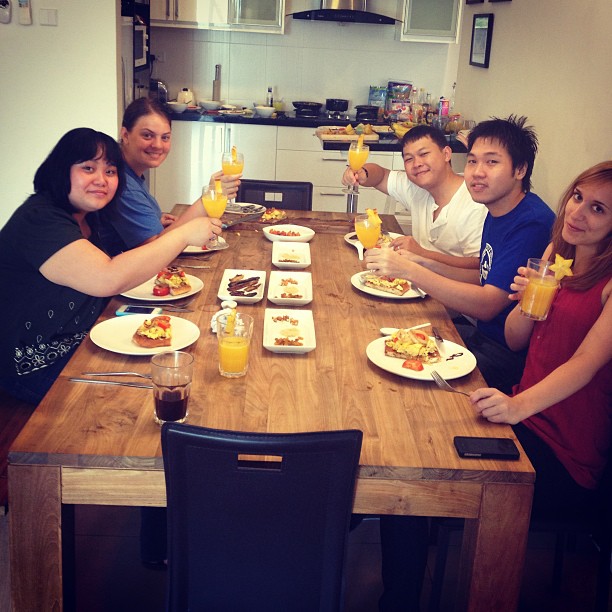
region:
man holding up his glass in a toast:
[340, 119, 491, 270]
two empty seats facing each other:
[155, 171, 366, 609]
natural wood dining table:
[2, 199, 542, 610]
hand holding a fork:
[428, 367, 523, 428]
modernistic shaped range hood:
[283, 0, 408, 29]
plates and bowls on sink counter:
[163, 96, 278, 118]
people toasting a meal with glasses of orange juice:
[0, 94, 611, 510]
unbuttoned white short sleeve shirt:
[385, 167, 489, 257]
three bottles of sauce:
[406, 84, 435, 125]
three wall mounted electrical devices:
[0, 0, 61, 28]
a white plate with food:
[88, 314, 200, 355]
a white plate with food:
[117, 271, 201, 301]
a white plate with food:
[185, 233, 222, 253]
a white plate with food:
[340, 231, 407, 249]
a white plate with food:
[348, 270, 422, 299]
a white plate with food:
[366, 335, 476, 383]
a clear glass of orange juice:
[212, 312, 253, 378]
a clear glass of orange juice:
[199, 182, 226, 250]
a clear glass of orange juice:
[516, 254, 564, 321]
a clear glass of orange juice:
[347, 210, 381, 278]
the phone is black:
[452, 432, 519, 461]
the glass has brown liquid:
[149, 349, 190, 424]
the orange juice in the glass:
[215, 311, 252, 378]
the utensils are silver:
[67, 365, 158, 390]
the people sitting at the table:
[1, 95, 608, 469]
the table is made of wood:
[9, 201, 536, 608]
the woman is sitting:
[431, 159, 609, 611]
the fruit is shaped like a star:
[547, 253, 575, 280]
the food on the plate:
[365, 330, 476, 381]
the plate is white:
[366, 333, 477, 381]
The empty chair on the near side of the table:
[143, 410, 368, 611]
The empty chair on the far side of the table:
[235, 169, 313, 219]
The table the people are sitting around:
[2, 197, 542, 609]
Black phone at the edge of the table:
[445, 427, 523, 462]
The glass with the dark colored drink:
[141, 342, 198, 429]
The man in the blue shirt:
[364, 113, 558, 384]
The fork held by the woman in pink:
[424, 367, 475, 398]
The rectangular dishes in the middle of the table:
[215, 237, 323, 359]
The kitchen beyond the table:
[119, 1, 472, 240]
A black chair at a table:
[150, 420, 385, 608]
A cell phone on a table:
[448, 430, 519, 462]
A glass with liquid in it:
[148, 349, 193, 429]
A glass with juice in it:
[212, 313, 253, 379]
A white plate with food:
[362, 331, 476, 380]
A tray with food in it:
[260, 304, 314, 358]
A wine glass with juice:
[201, 184, 228, 218]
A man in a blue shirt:
[362, 115, 556, 324]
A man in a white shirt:
[387, 162, 487, 256]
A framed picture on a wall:
[468, 11, 494, 66]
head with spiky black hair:
[465, 115, 538, 205]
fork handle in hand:
[428, 372, 517, 424]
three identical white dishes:
[263, 241, 315, 354]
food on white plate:
[91, 311, 202, 353]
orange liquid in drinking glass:
[213, 310, 253, 379]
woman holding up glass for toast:
[0, 128, 226, 396]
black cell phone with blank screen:
[454, 436, 519, 460]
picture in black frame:
[467, 12, 494, 67]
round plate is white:
[366, 331, 477, 382]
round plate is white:
[350, 267, 431, 298]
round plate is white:
[344, 230, 408, 248]